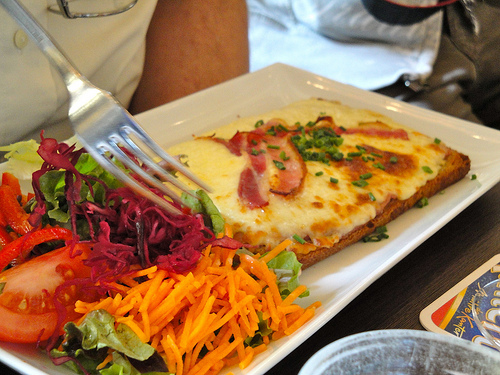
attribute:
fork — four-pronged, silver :
[2, 1, 214, 219]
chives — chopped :
[250, 112, 365, 184]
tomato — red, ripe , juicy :
[7, 235, 116, 349]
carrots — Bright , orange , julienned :
[97, 231, 294, 371]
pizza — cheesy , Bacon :
[164, 80, 485, 270]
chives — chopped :
[229, 92, 427, 220]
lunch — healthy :
[3, 82, 476, 367]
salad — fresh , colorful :
[0, 125, 306, 373]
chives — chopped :
[249, 92, 444, 256]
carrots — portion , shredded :
[69, 208, 321, 373]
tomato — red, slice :
[7, 237, 132, 347]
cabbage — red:
[12, 120, 338, 370]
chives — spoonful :
[287, 115, 352, 164]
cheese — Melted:
[162, 93, 450, 248]